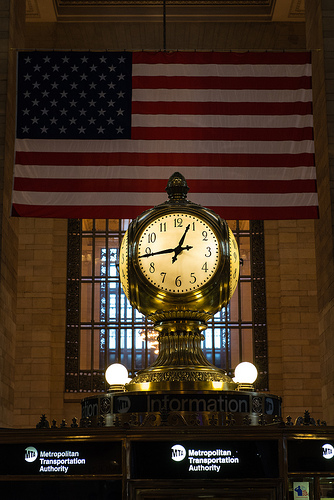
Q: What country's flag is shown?
A: Usa.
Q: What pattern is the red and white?
A: Stripes.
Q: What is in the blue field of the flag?
A: Stars.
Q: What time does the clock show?
A: 12:44.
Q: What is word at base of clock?
A: Information.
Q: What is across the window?
A: Metal bars.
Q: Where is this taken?
A: Train station.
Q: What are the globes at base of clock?
A: Lights.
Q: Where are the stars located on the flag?
A: The upper left hand corner.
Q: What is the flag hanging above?
A: A window.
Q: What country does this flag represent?
A: USA.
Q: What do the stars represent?
A: The states.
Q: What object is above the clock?
A: Flag.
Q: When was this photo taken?
A: Daytime.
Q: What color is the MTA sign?
A: Black.